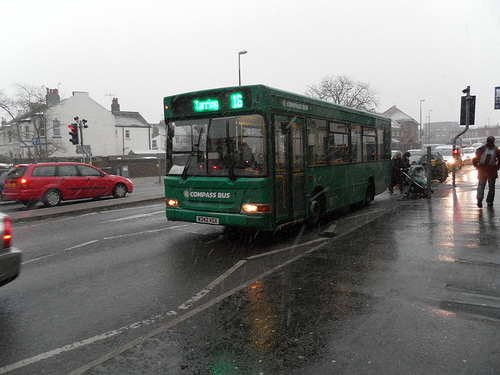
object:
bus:
[158, 82, 391, 239]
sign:
[191, 91, 246, 115]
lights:
[19, 177, 27, 184]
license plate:
[193, 212, 221, 226]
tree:
[300, 74, 378, 126]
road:
[2, 175, 498, 373]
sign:
[165, 162, 188, 177]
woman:
[389, 152, 406, 191]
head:
[485, 136, 494, 145]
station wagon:
[1, 160, 137, 207]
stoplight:
[66, 122, 81, 148]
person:
[400, 150, 413, 188]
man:
[470, 135, 499, 212]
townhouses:
[0, 86, 118, 165]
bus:
[391, 147, 448, 183]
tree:
[1, 88, 68, 164]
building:
[107, 97, 155, 158]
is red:
[67, 121, 78, 131]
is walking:
[470, 132, 499, 211]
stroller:
[397, 164, 435, 199]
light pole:
[233, 48, 250, 88]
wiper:
[217, 120, 240, 179]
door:
[266, 110, 292, 225]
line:
[245, 235, 328, 260]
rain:
[66, 236, 307, 349]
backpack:
[474, 143, 498, 168]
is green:
[189, 97, 220, 114]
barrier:
[9, 193, 165, 231]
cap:
[391, 150, 403, 158]